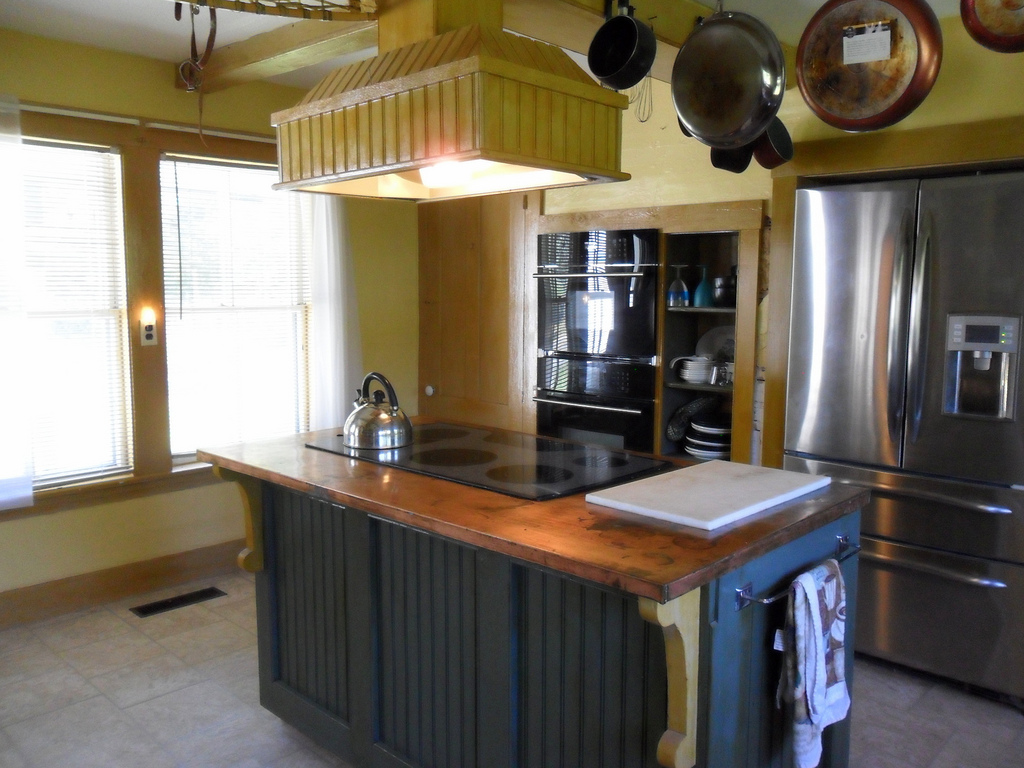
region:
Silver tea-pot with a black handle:
[335, 367, 413, 462]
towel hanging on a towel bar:
[768, 555, 857, 767]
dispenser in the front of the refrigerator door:
[924, 301, 1017, 429]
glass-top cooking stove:
[301, 405, 676, 517]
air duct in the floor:
[113, 573, 234, 628]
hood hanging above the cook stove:
[260, 5, 635, 224]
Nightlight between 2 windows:
[130, 296, 159, 329]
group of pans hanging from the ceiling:
[575, 0, 1022, 175]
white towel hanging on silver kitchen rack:
[780, 568, 894, 765]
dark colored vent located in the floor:
[120, 581, 225, 621]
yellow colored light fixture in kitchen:
[265, 52, 605, 218]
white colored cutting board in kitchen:
[586, 447, 822, 528]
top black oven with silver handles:
[523, 228, 663, 368]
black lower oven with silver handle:
[526, 359, 666, 449]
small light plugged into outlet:
[131, 301, 164, 369]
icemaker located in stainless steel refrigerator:
[937, 303, 1021, 437]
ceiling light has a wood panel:
[406, 85, 425, 162]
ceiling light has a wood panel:
[455, 67, 476, 151]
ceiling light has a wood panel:
[444, 79, 458, 156]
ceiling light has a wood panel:
[421, 79, 442, 153]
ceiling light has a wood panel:
[409, 85, 428, 158]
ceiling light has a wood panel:
[395, 86, 415, 163]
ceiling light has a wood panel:
[381, 90, 398, 163]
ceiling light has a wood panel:
[367, 95, 387, 163]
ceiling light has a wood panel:
[332, 109, 348, 167]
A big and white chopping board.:
[584, 456, 834, 534]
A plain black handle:
[359, 369, 398, 404]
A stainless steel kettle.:
[338, 373, 418, 449]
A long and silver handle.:
[903, 216, 927, 448]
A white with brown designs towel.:
[771, 557, 858, 766]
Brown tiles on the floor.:
[0, 648, 228, 763]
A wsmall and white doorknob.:
[420, 383, 434, 399]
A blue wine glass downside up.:
[689, 262, 713, 307]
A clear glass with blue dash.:
[666, 262, 692, 305]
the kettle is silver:
[339, 363, 406, 461]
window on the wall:
[160, 156, 320, 445]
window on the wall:
[4, 145, 128, 481]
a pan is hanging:
[672, 20, 777, 153]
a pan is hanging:
[792, 6, 941, 134]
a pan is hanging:
[580, 15, 657, 89]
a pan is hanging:
[956, 1, 1021, 52]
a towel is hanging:
[773, 567, 854, 763]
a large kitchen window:
[160, 158, 350, 459]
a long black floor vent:
[128, 581, 236, 619]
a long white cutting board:
[580, 455, 834, 560]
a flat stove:
[302, 404, 664, 502]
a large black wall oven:
[528, 233, 658, 455]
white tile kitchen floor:
[1, 569, 293, 766]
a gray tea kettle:
[337, 369, 411, 456]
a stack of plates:
[689, 417, 728, 465]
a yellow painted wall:
[5, 26, 318, 135]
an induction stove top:
[314, 415, 666, 501]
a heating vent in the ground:
[130, 587, 222, 620]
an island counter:
[202, 412, 869, 766]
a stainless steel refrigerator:
[788, 172, 1020, 716]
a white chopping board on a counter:
[585, 462, 832, 539]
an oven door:
[538, 227, 653, 363]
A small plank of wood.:
[483, 71, 506, 149]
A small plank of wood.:
[498, 76, 515, 149]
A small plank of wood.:
[522, 81, 539, 154]